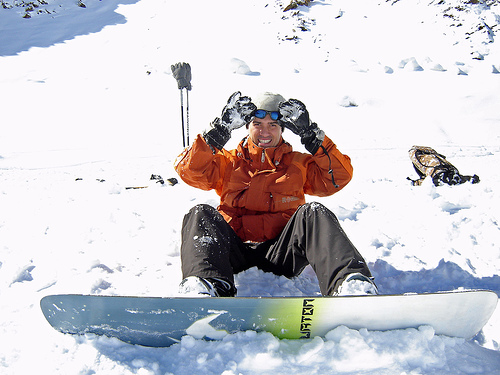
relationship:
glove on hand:
[278, 97, 320, 144] [268, 100, 328, 137]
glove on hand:
[209, 92, 256, 144] [220, 92, 256, 143]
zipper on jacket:
[254, 149, 269, 166] [174, 128, 369, 237]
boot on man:
[189, 255, 396, 299] [175, 79, 375, 284]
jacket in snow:
[174, 128, 369, 237] [13, 165, 179, 302]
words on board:
[299, 299, 315, 339] [40, 272, 495, 361]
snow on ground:
[61, 102, 128, 167] [165, 348, 326, 373]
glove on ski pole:
[171, 63, 187, 86] [179, 88, 184, 150]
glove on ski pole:
[171, 63, 187, 86] [185, 90, 191, 143]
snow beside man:
[0, 0, 499, 375] [175, 92, 378, 298]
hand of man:
[277, 97, 313, 136] [174, 91, 379, 297]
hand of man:
[217, 88, 258, 134] [174, 91, 379, 297]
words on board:
[300, 293, 314, 341] [40, 288, 490, 337]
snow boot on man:
[331, 267, 379, 299] [175, 92, 378, 298]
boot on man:
[178, 276, 237, 297] [175, 92, 378, 298]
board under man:
[17, 273, 497, 366] [157, 84, 402, 300]